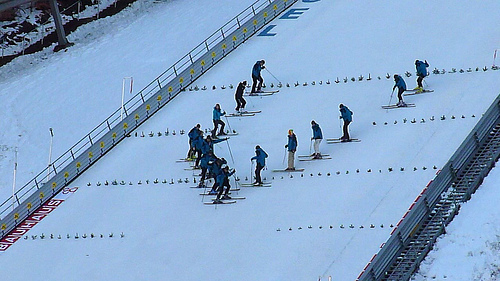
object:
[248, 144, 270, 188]
people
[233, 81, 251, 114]
man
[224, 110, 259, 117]
skis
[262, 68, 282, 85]
stick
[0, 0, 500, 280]
path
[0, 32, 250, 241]
boundary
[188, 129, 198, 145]
jacket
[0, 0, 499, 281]
snow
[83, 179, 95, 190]
objects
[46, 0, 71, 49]
tree trunk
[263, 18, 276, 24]
metal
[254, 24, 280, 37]
l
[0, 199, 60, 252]
banner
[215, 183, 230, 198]
pants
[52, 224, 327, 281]
slope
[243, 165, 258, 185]
ski pole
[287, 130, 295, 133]
hat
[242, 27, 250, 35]
signs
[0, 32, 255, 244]
fence